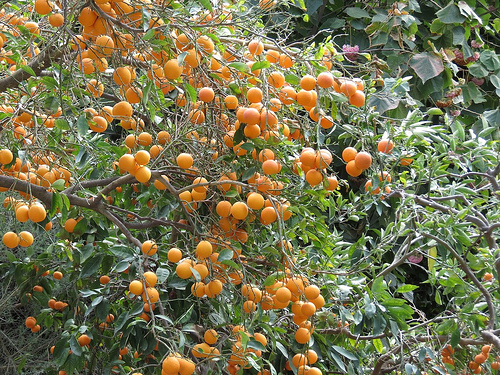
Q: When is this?
A: Daytime.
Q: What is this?
A: Fruits.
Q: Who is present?
A: No one.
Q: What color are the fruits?
A: Orange.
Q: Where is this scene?
A: Amongst mango trees.